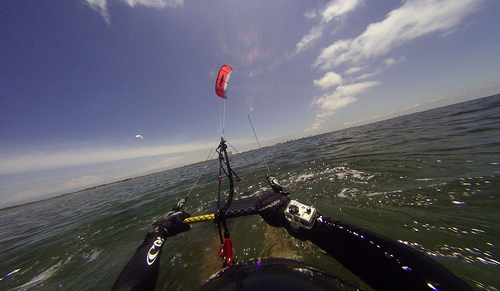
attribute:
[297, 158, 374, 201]
foam — white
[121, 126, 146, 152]
kite — red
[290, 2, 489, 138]
clouds — thin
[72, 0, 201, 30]
clouds — thin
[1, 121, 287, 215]
clouds — thin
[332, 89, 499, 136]
clouds — thin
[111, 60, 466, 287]
parachute — white, red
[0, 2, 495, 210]
sky — blue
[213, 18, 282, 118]
light — blur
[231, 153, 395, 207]
foam — white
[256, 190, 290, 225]
glove — black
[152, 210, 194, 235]
glove — black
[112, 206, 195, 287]
left arm — black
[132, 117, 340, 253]
harness — black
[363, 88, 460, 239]
water — greenish colored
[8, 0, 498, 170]
sky — bright, blue, clear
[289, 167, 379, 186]
wave — splashing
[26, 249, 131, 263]
wave — splashing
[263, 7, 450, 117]
clouds — white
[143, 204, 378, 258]
arms — black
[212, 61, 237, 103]
sail — large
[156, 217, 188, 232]
glove — black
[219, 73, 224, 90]
spot — black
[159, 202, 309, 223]
writing — white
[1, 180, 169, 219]
background — distant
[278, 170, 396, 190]
tops — white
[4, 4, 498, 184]
sky — blue, bright